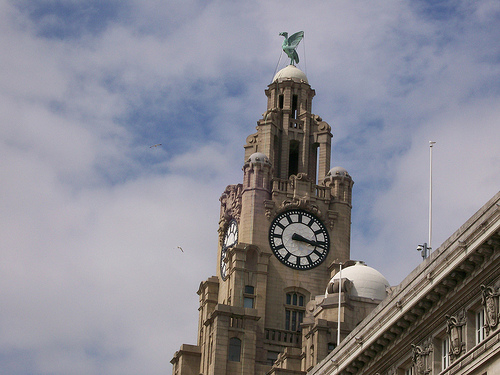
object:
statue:
[276, 30, 305, 68]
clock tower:
[171, 28, 355, 374]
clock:
[267, 209, 330, 270]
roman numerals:
[293, 254, 303, 268]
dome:
[271, 62, 309, 83]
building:
[298, 255, 391, 372]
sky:
[0, 0, 497, 374]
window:
[290, 290, 298, 306]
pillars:
[244, 78, 332, 185]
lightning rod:
[423, 140, 436, 260]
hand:
[289, 232, 324, 250]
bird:
[175, 246, 185, 255]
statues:
[442, 312, 466, 357]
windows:
[473, 310, 481, 331]